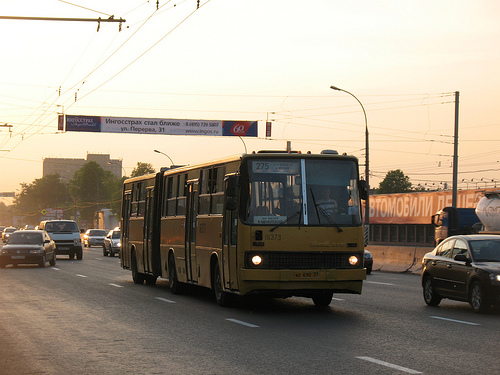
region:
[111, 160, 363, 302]
a bus of two cabins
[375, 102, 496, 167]
the sky as twilight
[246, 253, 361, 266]
the bus headlights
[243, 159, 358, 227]
the bus windshields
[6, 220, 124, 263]
several cars behind the bus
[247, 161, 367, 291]
the front view of the bus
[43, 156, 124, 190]
a building in the distance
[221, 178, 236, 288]
one door of the bus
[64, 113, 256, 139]
an unreadable sign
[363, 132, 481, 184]
several electrical cables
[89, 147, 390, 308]
yellow bus on the road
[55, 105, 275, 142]
road sign over the road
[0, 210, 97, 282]
two cars following the bus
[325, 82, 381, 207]
road light beside the road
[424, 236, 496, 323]
small car on the road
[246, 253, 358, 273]
two headlights on a bus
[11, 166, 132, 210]
trees in the distance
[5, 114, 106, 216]
sunlight reflection on the trees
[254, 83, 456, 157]
electrical wires long the street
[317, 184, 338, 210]
bus driver of the bus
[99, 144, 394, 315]
Yellow bus driving down the road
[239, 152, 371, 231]
Two large windows for drive to look out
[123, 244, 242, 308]
Three tires on side of bus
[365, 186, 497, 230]
White lettering on store front sign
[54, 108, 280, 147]
Red white and blue banner over street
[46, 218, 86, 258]
White van behind car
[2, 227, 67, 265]
Small black car on road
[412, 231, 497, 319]
Partial view of black car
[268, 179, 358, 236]
Wiper blades on bus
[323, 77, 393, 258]
Black street lamp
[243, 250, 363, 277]
headlights on the front of a bus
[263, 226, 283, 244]
number on the yellow part of the bus's front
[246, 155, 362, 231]
windshield on a bus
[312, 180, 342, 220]
person driving the bus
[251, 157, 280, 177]
number 275 on the bus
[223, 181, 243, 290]
front door on the bus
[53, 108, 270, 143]
banner hanging over the roadway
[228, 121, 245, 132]
number 60 on the banner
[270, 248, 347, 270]
grill on the front of the bus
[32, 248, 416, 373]
Dotted lines separating traffic lanes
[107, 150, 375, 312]
Large yellow bus on the street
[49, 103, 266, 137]
Banner advertisement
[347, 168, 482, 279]
Large building with red and white lettering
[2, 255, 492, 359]
Road with at least four lanes of traffic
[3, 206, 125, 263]
Numerous vehicles on the road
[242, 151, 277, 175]
Bus number 275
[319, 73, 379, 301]
Stree light on a pole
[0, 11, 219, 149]
Power lines running next to the road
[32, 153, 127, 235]
Large building in the background